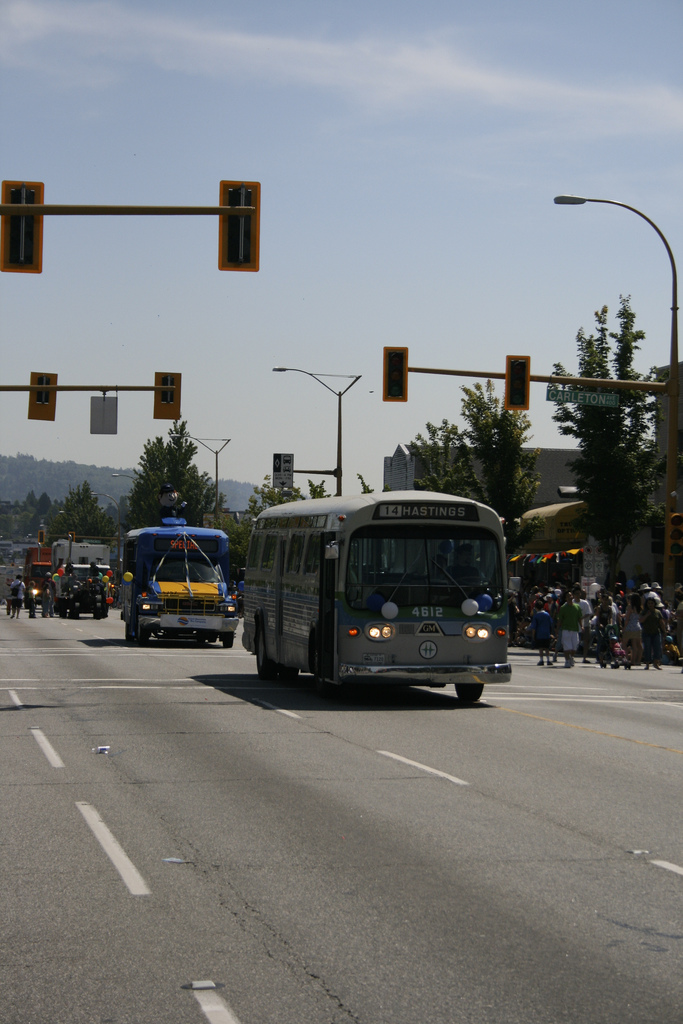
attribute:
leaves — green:
[602, 427, 629, 479]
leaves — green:
[420, 419, 443, 447]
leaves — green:
[459, 382, 486, 408]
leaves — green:
[522, 445, 539, 476]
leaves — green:
[170, 414, 196, 452]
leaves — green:
[143, 434, 167, 462]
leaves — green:
[130, 466, 157, 494]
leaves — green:
[199, 471, 230, 510]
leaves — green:
[170, 414, 192, 446]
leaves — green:
[141, 437, 170, 458]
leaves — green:
[198, 474, 224, 503]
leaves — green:
[125, 485, 161, 512]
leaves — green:
[40, 507, 64, 529]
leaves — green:
[64, 479, 95, 500]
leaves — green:
[83, 491, 104, 512]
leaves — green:
[94, 516, 118, 534]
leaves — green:
[143, 435, 171, 454]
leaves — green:
[186, 458, 203, 484]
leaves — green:
[163, 414, 192, 447]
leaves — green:
[189, 463, 213, 490]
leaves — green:
[145, 435, 174, 468]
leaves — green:
[126, 491, 148, 519]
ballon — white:
[381, 601, 400, 620]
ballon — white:
[459, 597, 480, 616]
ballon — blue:
[479, 592, 496, 611]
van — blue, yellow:
[122, 479, 236, 649]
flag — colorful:
[510, 550, 524, 564]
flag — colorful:
[525, 553, 536, 566]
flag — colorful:
[542, 551, 554, 564]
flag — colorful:
[564, 545, 583, 557]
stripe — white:
[54, 758, 205, 926]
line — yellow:
[479, 701, 662, 748]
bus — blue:
[117, 516, 241, 643]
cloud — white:
[1, 320, 661, 491]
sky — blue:
[1, 2, 662, 495]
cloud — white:
[1, 2, 659, 163]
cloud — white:
[2, 290, 661, 492]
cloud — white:
[2, 2, 662, 187]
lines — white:
[9, 683, 233, 1022]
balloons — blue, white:
[458, 587, 496, 618]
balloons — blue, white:
[365, 590, 401, 624]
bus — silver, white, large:
[235, 480, 515, 709]